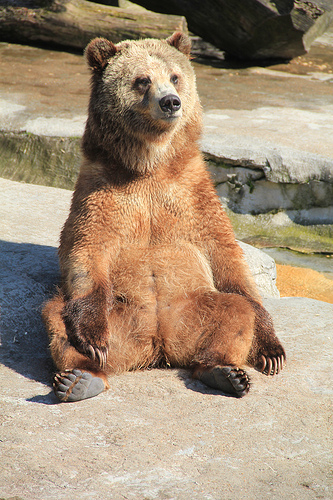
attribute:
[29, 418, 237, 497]
floor — part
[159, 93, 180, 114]
nose — black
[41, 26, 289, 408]
bear — brown, sitting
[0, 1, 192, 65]
log — brown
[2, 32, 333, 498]
ground — gray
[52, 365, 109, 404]
foot — part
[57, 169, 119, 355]
arm — part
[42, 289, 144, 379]
leg — bear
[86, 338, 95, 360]
finger — part